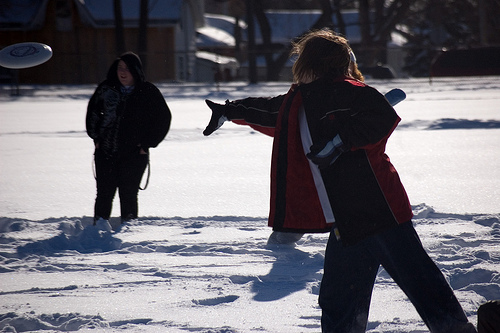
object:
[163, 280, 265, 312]
ground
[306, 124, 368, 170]
glove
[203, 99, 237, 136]
glove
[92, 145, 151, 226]
black pants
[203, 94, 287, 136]
arm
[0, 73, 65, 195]
ground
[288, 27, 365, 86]
brown hair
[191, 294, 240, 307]
foot prints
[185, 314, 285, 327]
snow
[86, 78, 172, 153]
black jacket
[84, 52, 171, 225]
person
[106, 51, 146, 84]
hood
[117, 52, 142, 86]
head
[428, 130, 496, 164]
snow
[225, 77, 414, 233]
coat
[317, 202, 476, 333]
pants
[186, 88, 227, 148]
glove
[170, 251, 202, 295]
snow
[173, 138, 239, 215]
ground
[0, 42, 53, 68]
frisbee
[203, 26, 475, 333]
girl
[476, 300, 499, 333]
backpack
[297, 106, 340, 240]
stripe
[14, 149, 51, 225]
snow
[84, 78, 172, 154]
coat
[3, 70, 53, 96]
air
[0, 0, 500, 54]
sky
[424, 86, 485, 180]
ground